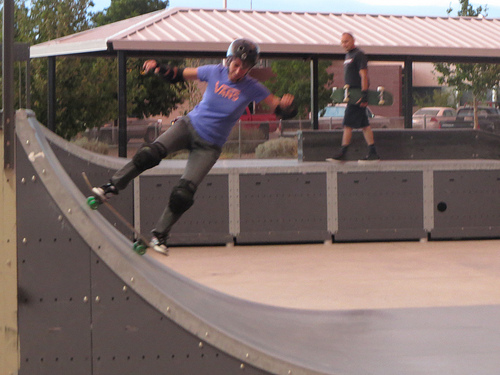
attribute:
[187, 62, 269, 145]
blue shirt — person's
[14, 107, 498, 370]
skateboard ramp — skate, board, white, large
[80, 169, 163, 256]
skateboard — long, green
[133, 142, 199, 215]
knee pads — black, skateboarding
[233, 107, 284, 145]
red pickup truck — bed of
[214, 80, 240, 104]
logo on shirt — woman's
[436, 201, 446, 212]
black hole — gray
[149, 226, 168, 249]
white sneaker — black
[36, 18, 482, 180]
pavillion — covered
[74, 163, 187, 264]
board — skate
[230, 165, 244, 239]
line — large, tan, black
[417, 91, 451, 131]
car — white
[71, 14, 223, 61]
roof — pink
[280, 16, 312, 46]
stripes — white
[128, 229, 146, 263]
wheels — green, white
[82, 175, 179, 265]
sneakers — black, white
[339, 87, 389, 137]
shorts — black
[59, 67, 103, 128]
trees — green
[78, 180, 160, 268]
wheels — green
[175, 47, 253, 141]
shirt — blue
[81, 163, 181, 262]
shoes — black, white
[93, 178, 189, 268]
shoes — white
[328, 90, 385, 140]
shorts — black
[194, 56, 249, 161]
shirt — blue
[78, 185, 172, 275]
wheels — green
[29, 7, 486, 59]
roof — red, long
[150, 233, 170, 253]
shoes — black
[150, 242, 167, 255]
soles — white